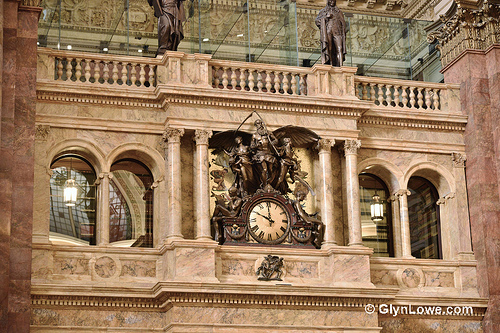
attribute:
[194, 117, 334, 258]
clock — old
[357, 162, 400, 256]
window — ancient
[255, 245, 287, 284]
emblem — bronze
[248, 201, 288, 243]
clock — ancient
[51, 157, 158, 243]
window — ancient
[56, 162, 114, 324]
window — ancient